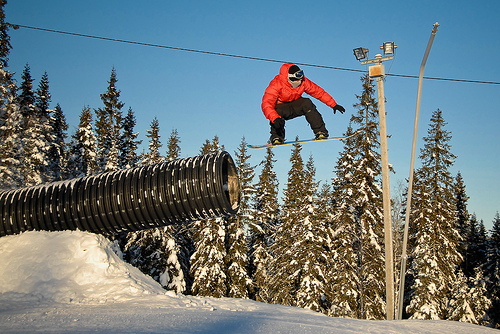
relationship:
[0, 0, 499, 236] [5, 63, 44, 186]
blue sky above tree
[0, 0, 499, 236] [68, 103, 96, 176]
blue sky above tree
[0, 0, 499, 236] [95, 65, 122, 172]
blue sky above tree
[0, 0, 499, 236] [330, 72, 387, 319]
blue sky above tree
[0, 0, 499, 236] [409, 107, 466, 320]
blue sky above tree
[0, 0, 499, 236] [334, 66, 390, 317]
blue sky above tree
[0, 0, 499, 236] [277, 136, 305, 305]
blue sky above tree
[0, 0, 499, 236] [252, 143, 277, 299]
blue sky above tree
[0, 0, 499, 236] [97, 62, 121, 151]
blue sky above tree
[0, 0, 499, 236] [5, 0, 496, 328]
blue sky above trees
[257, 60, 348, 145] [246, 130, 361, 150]
man on snowboard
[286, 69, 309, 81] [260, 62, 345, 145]
goggles on man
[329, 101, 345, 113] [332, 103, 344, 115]
glove on hand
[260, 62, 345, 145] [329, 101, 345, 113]
man wearing glove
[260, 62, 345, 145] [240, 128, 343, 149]
man on a board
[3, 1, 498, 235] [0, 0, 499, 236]
clouds in blue sky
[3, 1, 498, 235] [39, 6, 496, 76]
clouds in sky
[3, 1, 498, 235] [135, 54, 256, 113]
clouds in sky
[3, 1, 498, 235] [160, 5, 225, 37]
clouds in sky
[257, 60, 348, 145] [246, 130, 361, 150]
man riding a snowboard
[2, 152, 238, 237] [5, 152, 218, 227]
tube covered in snow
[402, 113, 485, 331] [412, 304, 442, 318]
tree covered in snow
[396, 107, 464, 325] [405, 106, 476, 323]
tree covered in snow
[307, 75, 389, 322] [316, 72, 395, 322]
tree covered in snow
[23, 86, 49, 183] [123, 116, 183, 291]
tree covered in snow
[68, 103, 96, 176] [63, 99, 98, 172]
tree covered in snow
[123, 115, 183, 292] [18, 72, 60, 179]
tree covered in snow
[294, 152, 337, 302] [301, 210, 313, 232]
tree covered with snow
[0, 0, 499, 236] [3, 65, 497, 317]
blue sky above trees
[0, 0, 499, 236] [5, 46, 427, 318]
blue sky above trees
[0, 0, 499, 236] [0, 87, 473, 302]
blue sky above trees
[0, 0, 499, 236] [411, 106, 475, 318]
blue sky above tree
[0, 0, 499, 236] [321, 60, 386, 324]
blue sky above tree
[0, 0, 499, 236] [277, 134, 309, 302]
blue sky above tree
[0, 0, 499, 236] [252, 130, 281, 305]
blue sky above tree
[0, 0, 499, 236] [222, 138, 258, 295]
blue sky above tree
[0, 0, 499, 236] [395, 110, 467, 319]
blue sky above tree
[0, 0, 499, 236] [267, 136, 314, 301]
blue sky above tree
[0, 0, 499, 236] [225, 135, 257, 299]
blue sky above tree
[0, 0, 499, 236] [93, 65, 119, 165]
blue sky above tree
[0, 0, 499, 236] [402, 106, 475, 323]
blue sky above tree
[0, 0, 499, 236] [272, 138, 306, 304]
blue sky above tree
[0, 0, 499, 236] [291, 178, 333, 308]
blue sky above tree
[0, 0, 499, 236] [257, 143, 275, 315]
blue sky above tree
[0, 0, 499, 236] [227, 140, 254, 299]
blue sky above tree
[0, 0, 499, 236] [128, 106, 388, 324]
blue sky above trees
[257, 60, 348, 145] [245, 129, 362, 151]
man and snowboard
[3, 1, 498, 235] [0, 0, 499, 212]
clouds in blue sky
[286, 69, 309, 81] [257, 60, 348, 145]
goggles worn by man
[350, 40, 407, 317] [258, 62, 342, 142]
light pole behind man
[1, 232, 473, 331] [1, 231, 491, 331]
ground covered in snow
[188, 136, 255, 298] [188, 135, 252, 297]
tree covered in snow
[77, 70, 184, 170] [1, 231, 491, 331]
tree covered in snow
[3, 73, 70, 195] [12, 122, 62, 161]
tree covered in snow